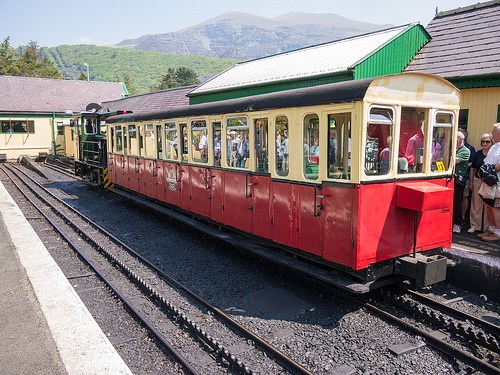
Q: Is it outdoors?
A: Yes, it is outdoors.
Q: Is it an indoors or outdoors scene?
A: It is outdoors.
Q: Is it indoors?
A: No, it is outdoors.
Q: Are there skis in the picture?
A: No, there are no skis.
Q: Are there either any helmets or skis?
A: No, there are no skis or helmets.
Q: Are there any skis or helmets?
A: No, there are no skis or helmets.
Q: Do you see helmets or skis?
A: No, there are no skis or helmets.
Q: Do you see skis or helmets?
A: No, there are no skis or helmets.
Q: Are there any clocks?
A: No, there are no clocks.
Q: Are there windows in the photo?
A: Yes, there is a window.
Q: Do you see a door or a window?
A: Yes, there is a window.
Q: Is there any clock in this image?
A: No, there are no clocks.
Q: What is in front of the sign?
A: The window is in front of the sign.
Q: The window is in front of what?
A: The window is in front of the sign.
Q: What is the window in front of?
A: The window is in front of the sign.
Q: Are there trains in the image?
A: Yes, there is a train.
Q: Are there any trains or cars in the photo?
A: Yes, there is a train.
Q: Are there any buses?
A: No, there are no buses.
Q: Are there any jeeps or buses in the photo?
A: No, there are no buses or jeeps.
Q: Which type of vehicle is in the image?
A: The vehicle is a train.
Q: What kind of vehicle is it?
A: The vehicle is a train.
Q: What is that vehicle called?
A: This is a train.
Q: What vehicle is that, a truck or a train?
A: This is a train.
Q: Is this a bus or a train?
A: This is a train.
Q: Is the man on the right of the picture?
A: Yes, the man is on the right of the image.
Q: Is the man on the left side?
A: No, the man is on the right of the image.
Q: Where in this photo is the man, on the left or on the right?
A: The man is on the right of the image.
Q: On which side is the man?
A: The man is on the right of the image.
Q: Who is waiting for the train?
A: The man is waiting for the train.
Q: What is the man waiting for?
A: The man is waiting for the train.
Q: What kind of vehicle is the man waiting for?
A: The man is waiting for the train.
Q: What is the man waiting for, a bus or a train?
A: The man is waiting for a train.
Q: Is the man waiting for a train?
A: Yes, the man is waiting for a train.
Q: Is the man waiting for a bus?
A: No, the man is waiting for a train.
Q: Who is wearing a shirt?
A: The man is wearing a shirt.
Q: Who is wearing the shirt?
A: The man is wearing a shirt.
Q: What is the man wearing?
A: The man is wearing a shirt.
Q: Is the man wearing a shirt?
A: Yes, the man is wearing a shirt.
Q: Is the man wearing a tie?
A: No, the man is wearing a shirt.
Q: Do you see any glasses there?
A: No, there are no glasses.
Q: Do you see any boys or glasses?
A: No, there are no glasses or boys.